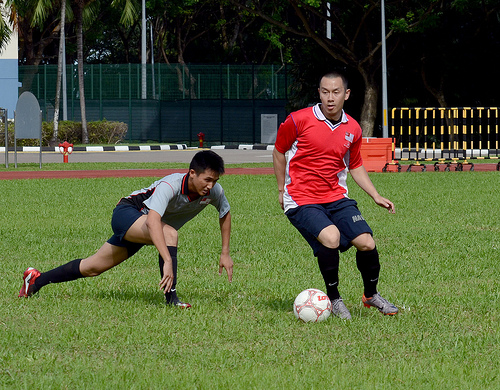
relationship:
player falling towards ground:
[20, 148, 232, 310] [3, 164, 498, 388]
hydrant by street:
[58, 139, 78, 162] [84, 143, 186, 168]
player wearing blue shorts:
[270, 70, 401, 319] [276, 193, 376, 258]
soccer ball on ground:
[292, 288, 332, 323] [386, 263, 495, 386]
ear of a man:
[183, 164, 199, 178] [20, 145, 244, 313]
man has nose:
[20, 145, 244, 313] [205, 180, 216, 191]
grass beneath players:
[62, 246, 357, 386] [146, 71, 436, 288]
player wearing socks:
[270, 70, 401, 319] [354, 250, 380, 302]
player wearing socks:
[270, 70, 401, 319] [317, 246, 339, 296]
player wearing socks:
[20, 148, 232, 310] [158, 243, 175, 300]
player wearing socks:
[20, 148, 232, 310] [33, 257, 82, 285]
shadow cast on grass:
[45, 289, 160, 303] [1, 172, 498, 389]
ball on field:
[293, 288, 332, 323] [417, 200, 484, 322]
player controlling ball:
[270, 70, 401, 319] [293, 288, 332, 323]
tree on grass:
[13, 2, 72, 141] [57, 140, 184, 145]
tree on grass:
[71, 0, 137, 144] [57, 140, 184, 145]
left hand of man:
[373, 197, 394, 211] [272, 65, 399, 324]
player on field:
[270, 70, 401, 319] [3, 163, 494, 384]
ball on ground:
[293, 288, 332, 323] [3, 164, 498, 388]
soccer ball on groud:
[292, 282, 332, 324] [288, 321, 337, 342]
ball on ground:
[293, 288, 332, 323] [0, 140, 499, 388]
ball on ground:
[293, 288, 332, 323] [216, 284, 496, 388]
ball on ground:
[293, 288, 332, 323] [214, 257, 457, 343]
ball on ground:
[291, 283, 333, 322] [3, 164, 498, 388]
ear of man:
[344, 89, 356, 100] [279, 58, 435, 308]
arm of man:
[214, 199, 234, 288] [179, 151, 228, 197]